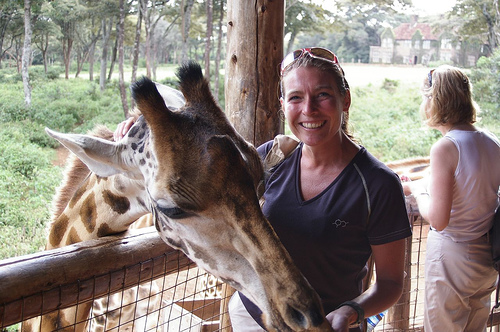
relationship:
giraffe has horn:
[13, 60, 341, 331] [125, 74, 176, 135]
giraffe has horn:
[13, 60, 341, 331] [173, 61, 217, 110]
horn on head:
[125, 74, 176, 135] [120, 61, 332, 331]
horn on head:
[173, 61, 217, 110] [120, 61, 332, 331]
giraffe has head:
[13, 60, 341, 331] [120, 61, 332, 331]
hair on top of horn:
[128, 76, 159, 102] [125, 74, 176, 135]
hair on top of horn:
[173, 59, 207, 87] [173, 61, 217, 110]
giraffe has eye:
[13, 60, 341, 331] [159, 197, 197, 221]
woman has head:
[226, 46, 412, 331] [279, 46, 351, 150]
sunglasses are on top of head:
[272, 46, 347, 92] [279, 46, 351, 150]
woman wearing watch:
[226, 46, 412, 331] [338, 296, 368, 327]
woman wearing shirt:
[226, 46, 412, 331] [240, 139, 416, 331]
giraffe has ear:
[13, 60, 341, 331] [153, 74, 189, 110]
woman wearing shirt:
[401, 63, 499, 331] [434, 125, 500, 244]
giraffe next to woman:
[13, 60, 341, 331] [226, 46, 412, 331]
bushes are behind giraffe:
[2, 65, 133, 256] [13, 60, 341, 331]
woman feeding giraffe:
[226, 46, 412, 331] [13, 60, 341, 331]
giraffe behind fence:
[13, 60, 341, 331] [2, 184, 496, 330]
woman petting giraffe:
[226, 46, 412, 331] [13, 60, 341, 331]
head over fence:
[120, 61, 332, 331] [2, 184, 496, 330]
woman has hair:
[226, 46, 412, 331] [270, 43, 351, 97]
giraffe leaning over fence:
[13, 60, 341, 331] [2, 184, 496, 330]